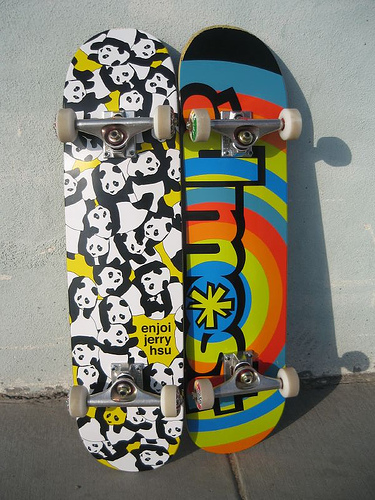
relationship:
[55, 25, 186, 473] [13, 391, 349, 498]
board leaning ground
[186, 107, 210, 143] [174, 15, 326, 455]
wheel in skate board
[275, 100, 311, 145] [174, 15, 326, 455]
wheel in skate board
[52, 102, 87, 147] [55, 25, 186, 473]
wheel in board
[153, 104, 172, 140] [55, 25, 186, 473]
wheel in board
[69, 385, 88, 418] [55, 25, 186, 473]
wheel in board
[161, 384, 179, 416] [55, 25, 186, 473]
wheel in board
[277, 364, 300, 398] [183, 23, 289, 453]
wheel on skateboard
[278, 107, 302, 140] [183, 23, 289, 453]
wheel on skateboard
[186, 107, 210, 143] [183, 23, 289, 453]
wheel on skateboard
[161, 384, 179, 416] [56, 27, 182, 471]
wheel on skateboard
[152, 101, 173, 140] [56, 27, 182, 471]
wheel on skateboard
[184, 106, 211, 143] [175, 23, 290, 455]
wheel on skate board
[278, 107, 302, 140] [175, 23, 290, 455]
wheel on skate board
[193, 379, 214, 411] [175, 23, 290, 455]
wheel on skate board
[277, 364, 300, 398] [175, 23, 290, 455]
wheel on skate board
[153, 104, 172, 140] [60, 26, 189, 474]
wheel on skate board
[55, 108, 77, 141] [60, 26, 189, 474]
wheel on skate board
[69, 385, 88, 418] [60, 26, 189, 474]
wheel on skate board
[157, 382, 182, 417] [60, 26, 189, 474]
wheel on skate board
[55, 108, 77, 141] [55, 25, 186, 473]
wheel on a board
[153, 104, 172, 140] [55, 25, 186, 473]
wheel on a board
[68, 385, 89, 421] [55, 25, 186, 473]
wheel on a board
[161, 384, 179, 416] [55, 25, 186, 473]
wheel on a board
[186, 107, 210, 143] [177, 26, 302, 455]
wheel on a skate board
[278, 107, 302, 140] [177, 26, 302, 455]
wheel on a skate board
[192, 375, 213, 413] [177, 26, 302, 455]
wheel on a skate board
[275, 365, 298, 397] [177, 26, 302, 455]
wheel on a skate board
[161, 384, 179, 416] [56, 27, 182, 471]
wheel of skateboard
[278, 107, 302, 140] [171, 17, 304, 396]
wheel of skateboard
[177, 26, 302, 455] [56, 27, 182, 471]
skate board by skateboard